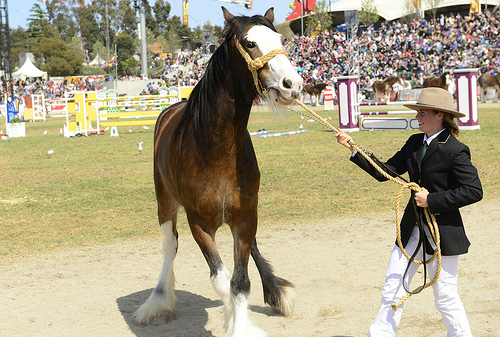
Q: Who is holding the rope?
A: Woman in brown hat.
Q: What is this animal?
A: A horse.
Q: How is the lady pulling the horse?
A: A rope.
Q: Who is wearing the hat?
A: A lady.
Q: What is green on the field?
A: Grass.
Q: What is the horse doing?
A: Racing.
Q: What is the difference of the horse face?
A: Color.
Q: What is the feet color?
A: White.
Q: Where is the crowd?
A: In stand.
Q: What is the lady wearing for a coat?
A: A blazer.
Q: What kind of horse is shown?
A: Show horse.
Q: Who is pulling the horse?
A: A woman.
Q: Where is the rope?
A: Attached to horse.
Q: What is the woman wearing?
A: Black jacket.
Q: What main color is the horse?
A: Brown.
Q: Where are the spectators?
A: Stands.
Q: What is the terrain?
A: Dirt.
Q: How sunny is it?
A: Very sunny.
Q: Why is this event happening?
A: Competition.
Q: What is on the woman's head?
A: Hat.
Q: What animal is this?
A: Horse.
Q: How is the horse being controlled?
A: With a rope and bridle.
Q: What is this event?
A: A horseback riding and jumping competition and exhibition.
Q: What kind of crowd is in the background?
A: Spectators.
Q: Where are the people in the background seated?
A: In the stands.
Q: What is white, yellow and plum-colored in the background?
A: The jumps.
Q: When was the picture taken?
A: Day time.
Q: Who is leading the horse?
A: A woman.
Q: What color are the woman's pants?
A: White.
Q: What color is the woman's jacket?
A: Black.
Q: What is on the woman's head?
A: A hat.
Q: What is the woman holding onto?
A: A rope.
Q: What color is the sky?
A: Blue.